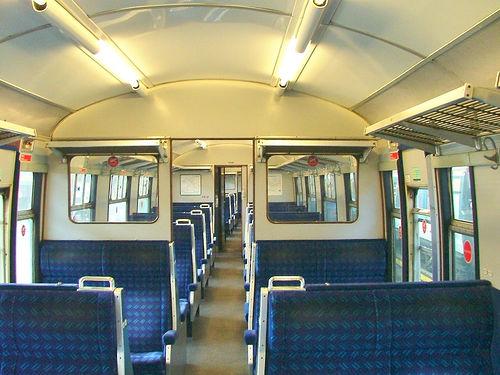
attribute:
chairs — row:
[5, 269, 499, 374]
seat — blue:
[244, 234, 388, 286]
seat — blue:
[234, 256, 499, 373]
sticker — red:
[458, 239, 473, 262]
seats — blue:
[237, 232, 374, 328]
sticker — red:
[308, 155, 316, 168]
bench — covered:
[31, 238, 176, 372]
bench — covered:
[43, 245, 174, 362]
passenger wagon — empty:
[0, 0, 499, 372]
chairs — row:
[95, 152, 252, 314]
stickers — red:
[390, 212, 477, 262]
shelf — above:
[359, 81, 497, 168]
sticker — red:
[14, 135, 46, 187]